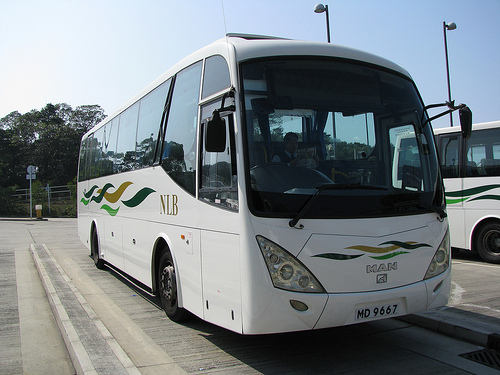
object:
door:
[196, 87, 242, 335]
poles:
[443, 21, 452, 104]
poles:
[325, 3, 332, 44]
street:
[0, 222, 494, 375]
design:
[310, 240, 434, 261]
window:
[235, 55, 445, 220]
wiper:
[288, 186, 325, 229]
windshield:
[237, 55, 446, 219]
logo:
[366, 262, 397, 274]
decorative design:
[80, 180, 157, 217]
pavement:
[0, 329, 61, 375]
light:
[447, 22, 457, 30]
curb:
[424, 313, 500, 349]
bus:
[392, 121, 500, 265]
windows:
[161, 53, 239, 213]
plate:
[354, 302, 398, 320]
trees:
[0, 102, 109, 217]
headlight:
[255, 234, 329, 293]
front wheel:
[158, 251, 183, 322]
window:
[78, 119, 112, 182]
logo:
[159, 194, 178, 215]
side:
[76, 36, 244, 335]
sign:
[26, 165, 39, 218]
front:
[234, 33, 452, 335]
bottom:
[243, 260, 452, 335]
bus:
[76, 32, 472, 335]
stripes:
[24, 252, 134, 367]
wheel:
[92, 228, 104, 269]